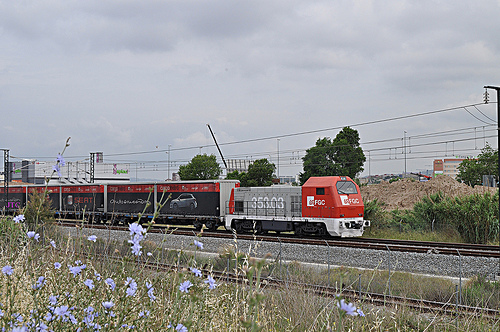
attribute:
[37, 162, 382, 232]
train — long, narrow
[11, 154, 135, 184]
buildings — pictured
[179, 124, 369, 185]
trees — green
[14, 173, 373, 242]
train — long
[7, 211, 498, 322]
train tracks — double set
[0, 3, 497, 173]
clouds — blue, white, grey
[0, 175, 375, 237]
train — silver and red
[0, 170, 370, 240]
train — red, white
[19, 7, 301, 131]
sky — cloudy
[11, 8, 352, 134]
sky — overcast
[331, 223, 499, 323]
tracks — railroad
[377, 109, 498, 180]
power lines — above